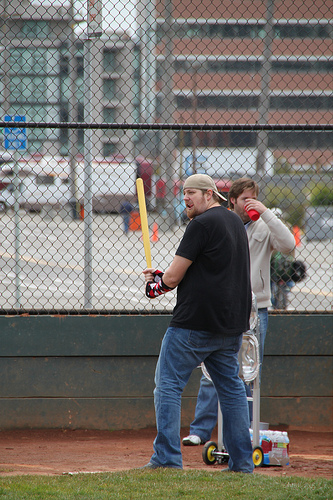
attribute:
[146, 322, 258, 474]
jeans — blue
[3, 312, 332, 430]
boards — green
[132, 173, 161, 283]
bat — large, yellow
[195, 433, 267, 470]
wheel — yellow, black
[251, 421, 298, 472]
bottles — water, bottled, pack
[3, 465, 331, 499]
grass — green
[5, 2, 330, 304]
fence — chain link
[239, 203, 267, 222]
cup — red, plastic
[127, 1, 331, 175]
building — multi story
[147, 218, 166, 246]
cone — orange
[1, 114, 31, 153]
sign — blue, handicap, white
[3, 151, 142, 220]
motorhome — brown, white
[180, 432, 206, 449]
shoe — white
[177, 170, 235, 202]
cap — baseball, beige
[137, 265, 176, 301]
gloves — black, red, white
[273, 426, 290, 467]
bottle — water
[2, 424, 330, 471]
dirt — brown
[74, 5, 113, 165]
pole — long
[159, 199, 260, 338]
t-shirt — black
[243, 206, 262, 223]
red — cup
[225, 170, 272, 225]
hair — brown